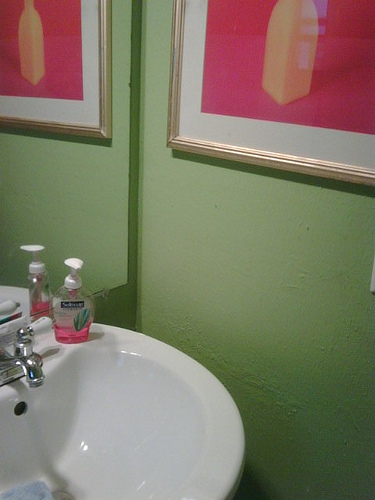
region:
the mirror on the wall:
[2, 0, 130, 328]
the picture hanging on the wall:
[164, 0, 374, 191]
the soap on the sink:
[45, 252, 98, 347]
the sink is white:
[3, 323, 247, 499]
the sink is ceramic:
[5, 323, 267, 496]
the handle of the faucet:
[5, 321, 60, 345]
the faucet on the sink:
[0, 314, 57, 401]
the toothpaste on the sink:
[1, 312, 27, 350]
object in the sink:
[1, 476, 56, 498]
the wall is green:
[143, 2, 373, 495]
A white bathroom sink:
[5, 315, 243, 495]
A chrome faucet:
[4, 315, 59, 386]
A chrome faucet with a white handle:
[13, 311, 59, 391]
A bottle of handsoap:
[49, 250, 99, 345]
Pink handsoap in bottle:
[43, 305, 109, 345]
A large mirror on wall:
[89, 112, 146, 315]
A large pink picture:
[156, 0, 373, 183]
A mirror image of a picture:
[3, 7, 117, 159]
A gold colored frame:
[163, 138, 366, 186]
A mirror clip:
[99, 281, 120, 302]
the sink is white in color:
[4, 313, 249, 497]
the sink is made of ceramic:
[1, 317, 254, 498]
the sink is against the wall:
[1, 314, 243, 498]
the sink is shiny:
[2, 316, 244, 499]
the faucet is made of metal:
[1, 316, 55, 394]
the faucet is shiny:
[0, 318, 57, 390]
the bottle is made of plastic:
[50, 285, 97, 343]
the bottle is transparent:
[51, 287, 93, 345]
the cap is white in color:
[61, 258, 85, 289]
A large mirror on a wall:
[0, 0, 132, 317]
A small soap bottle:
[51, 256, 94, 341]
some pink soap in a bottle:
[51, 325, 92, 343]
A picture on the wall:
[166, 1, 373, 184]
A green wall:
[95, 0, 374, 499]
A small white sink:
[0, 321, 246, 499]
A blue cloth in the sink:
[0, 478, 57, 499]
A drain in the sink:
[50, 488, 71, 499]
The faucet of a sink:
[2, 350, 45, 390]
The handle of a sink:
[15, 313, 55, 339]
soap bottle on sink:
[43, 256, 103, 348]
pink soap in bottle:
[54, 254, 105, 335]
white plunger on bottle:
[56, 245, 82, 296]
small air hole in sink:
[7, 401, 33, 416]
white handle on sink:
[12, 309, 52, 354]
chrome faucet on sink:
[1, 306, 38, 410]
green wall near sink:
[172, 201, 319, 339]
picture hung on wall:
[157, 21, 370, 151]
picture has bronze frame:
[148, 18, 373, 158]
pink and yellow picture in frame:
[206, 2, 342, 104]